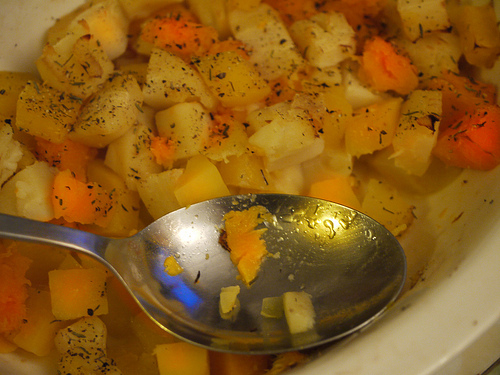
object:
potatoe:
[347, 98, 400, 160]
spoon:
[0, 191, 407, 355]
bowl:
[0, 1, 500, 375]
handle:
[0, 209, 103, 262]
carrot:
[439, 102, 499, 168]